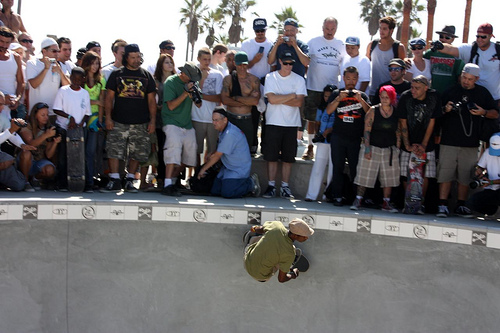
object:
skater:
[228, 202, 323, 281]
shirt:
[242, 219, 296, 287]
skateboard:
[242, 228, 310, 274]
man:
[240, 217, 320, 284]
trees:
[176, 0, 210, 60]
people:
[361, 16, 405, 107]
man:
[196, 105, 262, 200]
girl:
[348, 84, 408, 215]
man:
[159, 62, 203, 197]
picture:
[7, 8, 484, 294]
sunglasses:
[278, 61, 294, 66]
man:
[259, 49, 309, 202]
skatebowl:
[6, 186, 484, 326]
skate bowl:
[4, 184, 498, 331]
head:
[125, 43, 143, 68]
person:
[97, 41, 160, 194]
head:
[163, 56, 174, 72]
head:
[212, 108, 229, 131]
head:
[289, 219, 309, 243]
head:
[379, 84, 396, 106]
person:
[349, 85, 406, 215]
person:
[399, 73, 442, 215]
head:
[411, 75, 429, 100]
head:
[387, 58, 405, 81]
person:
[374, 57, 411, 109]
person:
[435, 59, 491, 218]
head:
[460, 70, 477, 89]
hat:
[288, 218, 315, 237]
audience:
[0, 0, 499, 221]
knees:
[210, 190, 221, 197]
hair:
[379, 84, 398, 106]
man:
[266, 18, 311, 77]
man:
[53, 65, 96, 193]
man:
[219, 50, 260, 157]